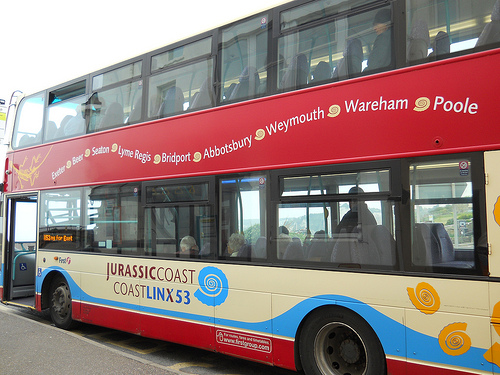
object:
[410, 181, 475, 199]
window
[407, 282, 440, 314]
swirls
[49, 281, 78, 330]
bus wheel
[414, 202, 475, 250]
window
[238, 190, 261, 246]
window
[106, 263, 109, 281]
text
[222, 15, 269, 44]
window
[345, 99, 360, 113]
letter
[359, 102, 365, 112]
letter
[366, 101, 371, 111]
letter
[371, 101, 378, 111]
letter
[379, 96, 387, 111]
letter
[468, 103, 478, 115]
text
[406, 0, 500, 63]
window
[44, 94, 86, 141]
window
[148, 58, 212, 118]
window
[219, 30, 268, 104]
window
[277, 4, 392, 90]
window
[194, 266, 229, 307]
swirl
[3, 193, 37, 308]
door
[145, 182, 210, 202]
window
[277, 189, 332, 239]
window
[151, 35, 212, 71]
window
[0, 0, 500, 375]
bus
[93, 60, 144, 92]
window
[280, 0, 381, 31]
window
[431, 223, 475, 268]
seats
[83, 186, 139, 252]
window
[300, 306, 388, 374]
tire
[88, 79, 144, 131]
window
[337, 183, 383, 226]
window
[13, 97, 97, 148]
window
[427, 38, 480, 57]
window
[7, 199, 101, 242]
window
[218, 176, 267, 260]
window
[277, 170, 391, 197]
window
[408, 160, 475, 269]
window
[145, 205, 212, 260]
window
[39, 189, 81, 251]
window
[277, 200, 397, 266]
window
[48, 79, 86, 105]
window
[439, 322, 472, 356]
swirls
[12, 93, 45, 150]
window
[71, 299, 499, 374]
bottom